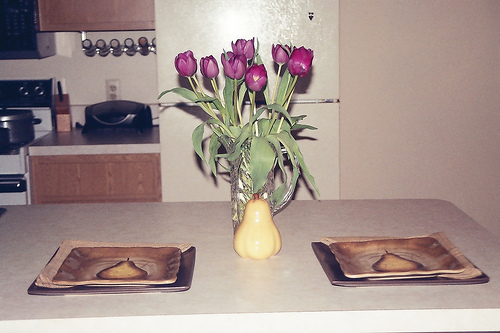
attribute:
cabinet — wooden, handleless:
[27, 151, 161, 202]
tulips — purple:
[168, 29, 317, 163]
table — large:
[3, 193, 499, 331]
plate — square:
[25, 237, 198, 299]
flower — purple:
[242, 57, 276, 145]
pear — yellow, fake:
[91, 252, 150, 287]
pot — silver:
[3, 104, 40, 148]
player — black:
[82, 98, 157, 137]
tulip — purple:
[287, 42, 319, 83]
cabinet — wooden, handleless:
[36, 2, 155, 31]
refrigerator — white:
[149, 0, 346, 203]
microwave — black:
[0, 3, 58, 62]